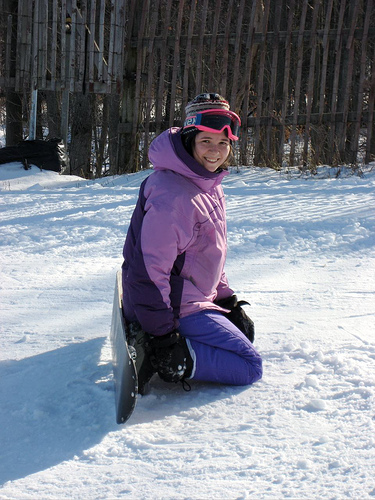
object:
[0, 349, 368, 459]
tracks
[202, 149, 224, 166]
smiling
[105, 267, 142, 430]
snowboard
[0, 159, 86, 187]
snow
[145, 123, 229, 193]
hood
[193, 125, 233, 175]
face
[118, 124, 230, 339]
jacket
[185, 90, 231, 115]
cap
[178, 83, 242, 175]
head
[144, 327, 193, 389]
glove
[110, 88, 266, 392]
girl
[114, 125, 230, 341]
coat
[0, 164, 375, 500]
snow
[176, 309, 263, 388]
pants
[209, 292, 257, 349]
glove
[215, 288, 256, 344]
hand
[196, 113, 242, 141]
eyewear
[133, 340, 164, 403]
feet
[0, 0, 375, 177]
fence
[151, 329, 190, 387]
hand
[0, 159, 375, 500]
field